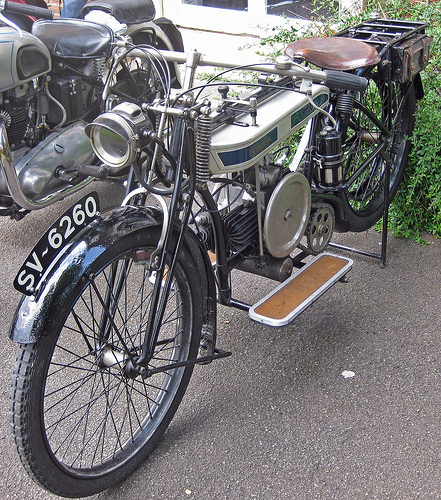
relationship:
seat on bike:
[283, 34, 381, 73] [7, 16, 434, 497]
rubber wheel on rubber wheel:
[341, 53, 415, 226] [336, 47, 421, 235]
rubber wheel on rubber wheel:
[11, 230, 205, 497] [6, 220, 215, 499]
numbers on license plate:
[13, 190, 98, 293] [11, 187, 102, 300]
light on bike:
[80, 109, 138, 173] [7, 14, 432, 496]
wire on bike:
[125, 61, 310, 181] [26, 29, 407, 447]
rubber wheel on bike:
[6, 220, 215, 499] [7, 16, 434, 497]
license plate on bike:
[13, 187, 104, 301] [7, 16, 434, 497]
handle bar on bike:
[200, 52, 368, 94] [7, 16, 434, 497]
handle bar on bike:
[53, 30, 187, 64] [7, 16, 434, 497]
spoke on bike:
[91, 378, 109, 467] [7, 16, 434, 497]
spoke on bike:
[122, 371, 136, 449] [7, 16, 434, 497]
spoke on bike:
[51, 366, 125, 452] [7, 16, 434, 497]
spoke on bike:
[121, 257, 129, 350] [7, 16, 434, 497]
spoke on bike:
[57, 343, 113, 371] [7, 16, 434, 497]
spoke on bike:
[150, 331, 184, 359] [7, 16, 434, 497]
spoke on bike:
[44, 375, 129, 433] [7, 16, 434, 497]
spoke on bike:
[47, 357, 120, 378] [7, 16, 434, 497]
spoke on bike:
[114, 377, 159, 405] [7, 16, 434, 497]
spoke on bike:
[101, 271, 127, 334] [7, 16, 434, 497]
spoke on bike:
[125, 291, 153, 320] [7, 16, 434, 497]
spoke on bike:
[63, 320, 127, 355] [7, 16, 434, 497]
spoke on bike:
[97, 268, 142, 357] [7, 16, 434, 497]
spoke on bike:
[116, 364, 139, 445] [7, 16, 434, 497]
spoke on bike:
[52, 340, 96, 367] [7, 16, 434, 497]